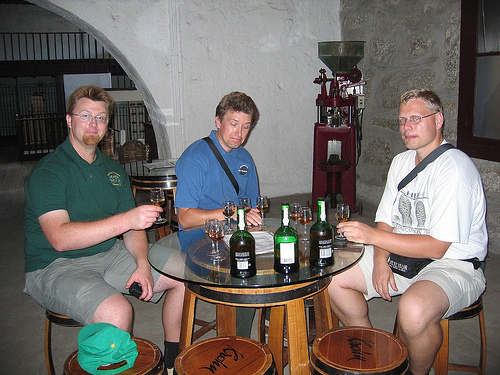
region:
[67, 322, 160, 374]
green hat sitting on top of the stool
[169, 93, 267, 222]
man wearing blue shirt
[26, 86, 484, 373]
men holding glasses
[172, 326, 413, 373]
black lettering on wooden stools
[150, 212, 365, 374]
green bottles on top of table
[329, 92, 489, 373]
man wearing white and gray shirt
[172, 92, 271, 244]
man looking down at the glass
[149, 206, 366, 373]
wooden and glass table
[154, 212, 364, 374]
white paper sitting on table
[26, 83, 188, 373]
man holding black object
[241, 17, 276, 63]
part of a wa;ll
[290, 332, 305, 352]
part of a stand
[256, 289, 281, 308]
edge of a table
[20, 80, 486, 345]
Three men drinking together.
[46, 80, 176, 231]
Smiling man holding a glass.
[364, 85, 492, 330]
Seated man wearing white t-shirt and short.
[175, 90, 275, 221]
Man looking at his glass.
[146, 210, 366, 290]
Drinks and glasses on a glass round table.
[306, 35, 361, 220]
Old alambic decorating the corner.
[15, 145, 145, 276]
Man wearing a green shirt.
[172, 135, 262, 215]
Man wearing blue shirt.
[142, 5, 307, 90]
Grey stone painted wall.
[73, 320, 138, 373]
Green cap on a stool chair.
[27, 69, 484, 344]
three men at a table drinking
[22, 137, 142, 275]
a man wearing a green shirt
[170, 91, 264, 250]
a man wearing a blue shirt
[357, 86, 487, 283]
a man wearing a white shirt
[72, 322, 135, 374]
a green baseball hat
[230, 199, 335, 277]
three green glass bottles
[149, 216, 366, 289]
a round glass table with glasses and bottles on it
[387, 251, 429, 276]
a black fanny pack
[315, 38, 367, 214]
a bottling machine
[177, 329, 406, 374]
two empty wooden stools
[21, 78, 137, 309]
this is a man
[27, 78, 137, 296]
the man is sitted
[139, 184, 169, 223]
he is holding a glass of wine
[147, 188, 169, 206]
the glass is small in number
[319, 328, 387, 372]
this is a stool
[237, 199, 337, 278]
these are the bottles of wine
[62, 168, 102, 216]
the t shirt in color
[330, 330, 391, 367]
the stool is brown in color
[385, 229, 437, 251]
this is a hand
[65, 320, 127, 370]
this is a cap